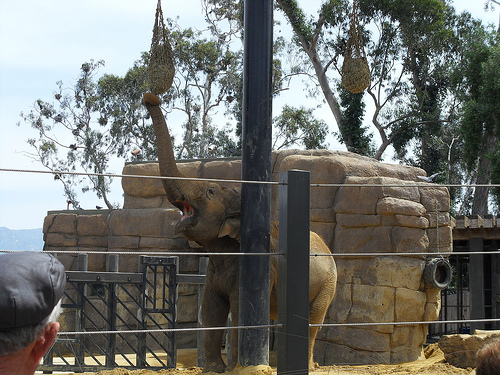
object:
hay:
[416, 353, 428, 365]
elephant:
[137, 90, 340, 373]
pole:
[239, 2, 270, 368]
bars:
[64, 278, 181, 367]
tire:
[421, 256, 457, 291]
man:
[0, 247, 70, 371]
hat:
[1, 249, 69, 331]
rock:
[346, 278, 401, 335]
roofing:
[130, 152, 238, 168]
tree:
[281, 21, 396, 157]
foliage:
[421, 7, 433, 24]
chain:
[430, 196, 443, 252]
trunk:
[141, 93, 194, 200]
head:
[0, 255, 65, 375]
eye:
[203, 188, 216, 197]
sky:
[42, 17, 92, 35]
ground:
[310, 361, 443, 374]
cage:
[175, 247, 197, 367]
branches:
[364, 62, 445, 160]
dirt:
[328, 362, 354, 374]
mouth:
[173, 201, 199, 233]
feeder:
[146, 1, 178, 94]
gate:
[69, 261, 93, 310]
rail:
[137, 251, 178, 311]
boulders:
[77, 211, 114, 237]